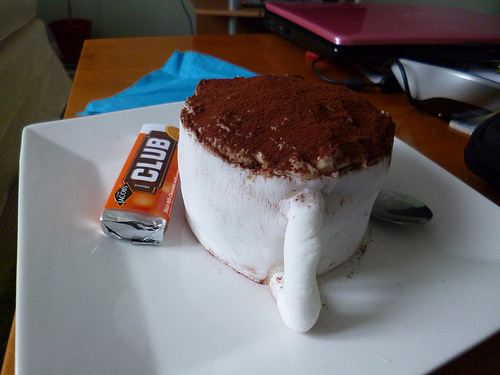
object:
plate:
[14, 100, 498, 375]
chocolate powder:
[180, 74, 397, 174]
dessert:
[177, 74, 396, 333]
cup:
[176, 74, 395, 333]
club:
[130, 138, 170, 183]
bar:
[99, 124, 179, 246]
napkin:
[75, 50, 259, 117]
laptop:
[264, 0, 500, 63]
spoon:
[371, 189, 433, 226]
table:
[1, 33, 500, 374]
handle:
[269, 189, 325, 332]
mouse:
[389, 58, 500, 119]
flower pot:
[48, 18, 92, 64]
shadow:
[267, 0, 367, 36]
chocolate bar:
[99, 123, 179, 244]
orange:
[166, 125, 179, 141]